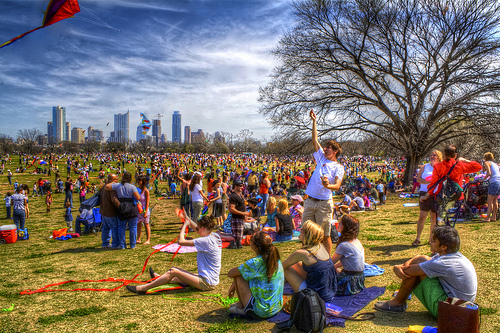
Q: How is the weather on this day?
A: It is cloudy.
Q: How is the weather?
A: It is cloudy.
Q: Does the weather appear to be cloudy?
A: Yes, it is cloudy.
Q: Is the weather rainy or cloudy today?
A: It is cloudy.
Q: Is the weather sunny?
A: No, it is cloudy.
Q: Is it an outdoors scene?
A: Yes, it is outdoors.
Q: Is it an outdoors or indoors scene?
A: It is outdoors.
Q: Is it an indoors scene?
A: No, it is outdoors.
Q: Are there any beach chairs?
A: No, there are no beach chairs.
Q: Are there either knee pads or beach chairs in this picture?
A: No, there are no beach chairs or knee pads.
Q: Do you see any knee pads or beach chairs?
A: No, there are no beach chairs or knee pads.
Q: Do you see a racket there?
A: No, there are no rackets.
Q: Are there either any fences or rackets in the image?
A: No, there are no rackets or fences.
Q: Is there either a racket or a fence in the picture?
A: No, there are no rackets or fences.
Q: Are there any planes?
A: No, there are no planes.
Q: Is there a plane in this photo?
A: No, there are no airplanes.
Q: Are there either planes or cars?
A: No, there are no planes or cars.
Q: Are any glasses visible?
A: No, there are no glasses.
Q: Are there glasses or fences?
A: No, there are no glasses or fences.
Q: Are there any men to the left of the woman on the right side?
A: Yes, there is a man to the left of the woman.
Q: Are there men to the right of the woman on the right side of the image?
A: No, the man is to the left of the woman.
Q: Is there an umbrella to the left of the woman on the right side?
A: No, there is a man to the left of the woman.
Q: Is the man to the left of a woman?
A: Yes, the man is to the left of a woman.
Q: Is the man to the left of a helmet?
A: No, the man is to the left of a woman.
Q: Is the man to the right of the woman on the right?
A: No, the man is to the left of the woman.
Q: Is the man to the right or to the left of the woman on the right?
A: The man is to the left of the woman.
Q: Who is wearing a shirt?
A: The man is wearing a shirt.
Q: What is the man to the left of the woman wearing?
A: The man is wearing a shirt.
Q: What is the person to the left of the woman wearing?
A: The man is wearing a shirt.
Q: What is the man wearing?
A: The man is wearing a shirt.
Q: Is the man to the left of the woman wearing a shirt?
A: Yes, the man is wearing a shirt.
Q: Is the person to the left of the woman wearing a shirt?
A: Yes, the man is wearing a shirt.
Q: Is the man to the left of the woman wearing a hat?
A: No, the man is wearing a shirt.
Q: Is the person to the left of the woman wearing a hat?
A: No, the man is wearing a shirt.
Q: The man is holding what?
A: The man is holding the kite.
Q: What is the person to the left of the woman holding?
A: The man is holding the kite.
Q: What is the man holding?
A: The man is holding the kite.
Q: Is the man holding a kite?
A: Yes, the man is holding a kite.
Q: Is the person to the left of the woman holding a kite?
A: Yes, the man is holding a kite.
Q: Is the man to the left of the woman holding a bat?
A: No, the man is holding a kite.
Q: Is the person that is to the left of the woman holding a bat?
A: No, the man is holding a kite.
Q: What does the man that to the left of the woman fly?
A: The man flies the kite.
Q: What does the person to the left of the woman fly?
A: The man flies the kite.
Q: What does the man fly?
A: The man flies the kite.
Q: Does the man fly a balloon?
A: No, the man flies the kite.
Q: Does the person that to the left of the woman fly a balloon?
A: No, the man flies the kite.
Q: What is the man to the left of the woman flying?
A: The man is flying the kite.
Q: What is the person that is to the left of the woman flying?
A: The man is flying the kite.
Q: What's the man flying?
A: The man is flying the kite.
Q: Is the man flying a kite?
A: Yes, the man is flying a kite.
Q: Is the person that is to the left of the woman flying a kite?
A: Yes, the man is flying a kite.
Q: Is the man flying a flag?
A: No, the man is flying a kite.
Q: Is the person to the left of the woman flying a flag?
A: No, the man is flying a kite.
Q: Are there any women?
A: Yes, there is a woman.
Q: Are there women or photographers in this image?
A: Yes, there is a woman.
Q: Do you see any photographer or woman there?
A: Yes, there is a woman.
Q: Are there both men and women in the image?
A: Yes, there are both a woman and a man.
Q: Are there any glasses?
A: No, there are no glasses.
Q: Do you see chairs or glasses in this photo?
A: No, there are no glasses or chairs.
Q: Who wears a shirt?
A: The woman wears a shirt.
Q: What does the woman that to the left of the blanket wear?
A: The woman wears a shirt.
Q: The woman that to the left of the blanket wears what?
A: The woman wears a shirt.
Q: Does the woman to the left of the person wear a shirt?
A: Yes, the woman wears a shirt.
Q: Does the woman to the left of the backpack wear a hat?
A: No, the woman wears a shirt.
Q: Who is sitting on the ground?
A: The woman is sitting on the ground.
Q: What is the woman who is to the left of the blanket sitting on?
A: The woman is sitting on the ground.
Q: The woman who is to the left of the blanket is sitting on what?
A: The woman is sitting on the ground.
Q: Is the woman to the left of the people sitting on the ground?
A: Yes, the woman is sitting on the ground.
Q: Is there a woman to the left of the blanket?
A: Yes, there is a woman to the left of the blanket.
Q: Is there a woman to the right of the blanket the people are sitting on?
A: No, the woman is to the left of the blanket.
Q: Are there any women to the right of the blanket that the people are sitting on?
A: No, the woman is to the left of the blanket.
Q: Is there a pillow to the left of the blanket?
A: No, there is a woman to the left of the blanket.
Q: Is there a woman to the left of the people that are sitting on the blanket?
A: Yes, there is a woman to the left of the people.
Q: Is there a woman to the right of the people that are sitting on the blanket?
A: No, the woman is to the left of the people.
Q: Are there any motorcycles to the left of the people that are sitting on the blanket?
A: No, there is a woman to the left of the people.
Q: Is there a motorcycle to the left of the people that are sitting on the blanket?
A: No, there is a woman to the left of the people.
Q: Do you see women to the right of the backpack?
A: No, the woman is to the left of the backpack.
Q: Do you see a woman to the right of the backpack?
A: No, the woman is to the left of the backpack.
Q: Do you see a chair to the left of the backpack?
A: No, there is a woman to the left of the backpack.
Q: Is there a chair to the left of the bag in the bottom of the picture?
A: No, there is a woman to the left of the backpack.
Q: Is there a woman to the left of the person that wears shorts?
A: Yes, there is a woman to the left of the person.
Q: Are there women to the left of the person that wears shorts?
A: Yes, there is a woman to the left of the person.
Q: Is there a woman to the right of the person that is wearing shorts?
A: No, the woman is to the left of the person.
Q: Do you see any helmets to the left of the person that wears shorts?
A: No, there is a woman to the left of the person.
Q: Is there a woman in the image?
A: Yes, there is a woman.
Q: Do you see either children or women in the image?
A: Yes, there is a woman.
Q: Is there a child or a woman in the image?
A: Yes, there is a woman.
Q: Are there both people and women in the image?
A: Yes, there are both a woman and a person.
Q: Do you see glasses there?
A: No, there are no glasses.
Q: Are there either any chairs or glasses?
A: No, there are no glasses or chairs.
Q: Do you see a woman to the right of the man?
A: Yes, there is a woman to the right of the man.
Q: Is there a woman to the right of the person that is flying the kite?
A: Yes, there is a woman to the right of the man.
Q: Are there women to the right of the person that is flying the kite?
A: Yes, there is a woman to the right of the man.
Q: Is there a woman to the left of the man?
A: No, the woman is to the right of the man.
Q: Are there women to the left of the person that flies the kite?
A: No, the woman is to the right of the man.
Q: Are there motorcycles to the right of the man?
A: No, there is a woman to the right of the man.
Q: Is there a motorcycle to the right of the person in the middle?
A: No, there is a woman to the right of the man.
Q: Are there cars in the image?
A: No, there are no cars.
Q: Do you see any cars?
A: No, there are no cars.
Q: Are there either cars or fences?
A: No, there are no cars or fences.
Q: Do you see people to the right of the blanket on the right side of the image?
A: Yes, there is a person to the right of the blanket.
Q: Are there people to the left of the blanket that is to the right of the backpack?
A: No, the person is to the right of the blanket.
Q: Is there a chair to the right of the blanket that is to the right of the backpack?
A: No, there is a person to the right of the blanket.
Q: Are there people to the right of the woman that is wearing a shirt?
A: Yes, there is a person to the right of the woman.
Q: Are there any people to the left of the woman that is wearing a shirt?
A: No, the person is to the right of the woman.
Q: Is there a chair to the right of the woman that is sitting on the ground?
A: No, there is a person to the right of the woman.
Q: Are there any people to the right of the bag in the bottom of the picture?
A: Yes, there is a person to the right of the backpack.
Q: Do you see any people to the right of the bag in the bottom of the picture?
A: Yes, there is a person to the right of the backpack.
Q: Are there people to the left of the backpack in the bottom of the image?
A: No, the person is to the right of the backpack.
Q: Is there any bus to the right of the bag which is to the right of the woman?
A: No, there is a person to the right of the backpack.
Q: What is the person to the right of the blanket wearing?
A: The person is wearing shorts.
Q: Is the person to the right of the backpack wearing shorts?
A: Yes, the person is wearing shorts.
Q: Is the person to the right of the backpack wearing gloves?
A: No, the person is wearing shorts.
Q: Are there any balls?
A: No, there are no balls.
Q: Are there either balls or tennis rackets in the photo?
A: No, there are no balls or tennis rackets.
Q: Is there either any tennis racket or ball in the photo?
A: No, there are no balls or rackets.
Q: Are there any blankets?
A: Yes, there is a blanket.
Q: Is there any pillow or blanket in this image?
A: Yes, there is a blanket.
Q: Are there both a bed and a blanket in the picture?
A: No, there is a blanket but no beds.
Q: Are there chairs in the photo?
A: No, there are no chairs.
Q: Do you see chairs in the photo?
A: No, there are no chairs.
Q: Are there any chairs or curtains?
A: No, there are no chairs or curtains.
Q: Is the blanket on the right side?
A: Yes, the blanket is on the right of the image.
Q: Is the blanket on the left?
A: No, the blanket is on the right of the image.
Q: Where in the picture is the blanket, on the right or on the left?
A: The blanket is on the right of the image.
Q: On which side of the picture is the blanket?
A: The blanket is on the right of the image.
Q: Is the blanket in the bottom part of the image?
A: Yes, the blanket is in the bottom of the image.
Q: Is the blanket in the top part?
A: No, the blanket is in the bottom of the image.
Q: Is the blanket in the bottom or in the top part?
A: The blanket is in the bottom of the image.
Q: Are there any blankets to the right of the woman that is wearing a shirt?
A: Yes, there is a blanket to the right of the woman.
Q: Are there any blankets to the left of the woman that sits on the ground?
A: No, the blanket is to the right of the woman.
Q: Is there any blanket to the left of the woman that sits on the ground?
A: No, the blanket is to the right of the woman.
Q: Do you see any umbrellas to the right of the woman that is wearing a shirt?
A: No, there is a blanket to the right of the woman.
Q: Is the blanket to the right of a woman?
A: Yes, the blanket is to the right of a woman.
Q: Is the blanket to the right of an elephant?
A: No, the blanket is to the right of a woman.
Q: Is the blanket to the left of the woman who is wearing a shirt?
A: No, the blanket is to the right of the woman.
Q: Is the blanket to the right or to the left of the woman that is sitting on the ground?
A: The blanket is to the right of the woman.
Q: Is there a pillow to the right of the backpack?
A: No, there is a blanket to the right of the backpack.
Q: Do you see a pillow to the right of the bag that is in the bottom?
A: No, there is a blanket to the right of the backpack.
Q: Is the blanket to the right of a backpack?
A: Yes, the blanket is to the right of a backpack.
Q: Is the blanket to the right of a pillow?
A: No, the blanket is to the right of a backpack.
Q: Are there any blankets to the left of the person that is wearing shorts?
A: Yes, there is a blanket to the left of the person.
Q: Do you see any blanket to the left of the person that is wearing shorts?
A: Yes, there is a blanket to the left of the person.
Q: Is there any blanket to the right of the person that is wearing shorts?
A: No, the blanket is to the left of the person.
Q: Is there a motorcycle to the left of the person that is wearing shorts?
A: No, there is a blanket to the left of the person.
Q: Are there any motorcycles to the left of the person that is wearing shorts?
A: No, there is a blanket to the left of the person.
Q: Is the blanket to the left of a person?
A: Yes, the blanket is to the left of a person.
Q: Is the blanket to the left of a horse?
A: No, the blanket is to the left of a person.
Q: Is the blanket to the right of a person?
A: No, the blanket is to the left of a person.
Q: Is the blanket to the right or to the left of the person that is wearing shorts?
A: The blanket is to the left of the person.